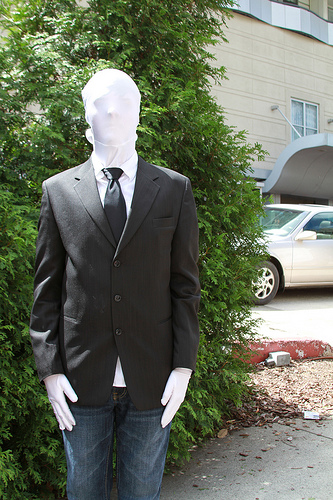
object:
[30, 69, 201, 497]
man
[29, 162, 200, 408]
suit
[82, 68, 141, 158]
mask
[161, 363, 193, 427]
glove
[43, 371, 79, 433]
glove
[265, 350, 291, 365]
box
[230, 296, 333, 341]
driveway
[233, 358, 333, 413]
chips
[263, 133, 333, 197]
awning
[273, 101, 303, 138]
pole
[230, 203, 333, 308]
car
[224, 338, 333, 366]
curb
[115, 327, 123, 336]
button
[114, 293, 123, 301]
button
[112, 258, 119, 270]
button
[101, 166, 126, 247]
tie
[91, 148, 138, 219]
shirt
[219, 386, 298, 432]
leaves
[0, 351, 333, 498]
ground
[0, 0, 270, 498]
bush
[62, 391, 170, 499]
jeans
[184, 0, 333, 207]
building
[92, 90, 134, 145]
face